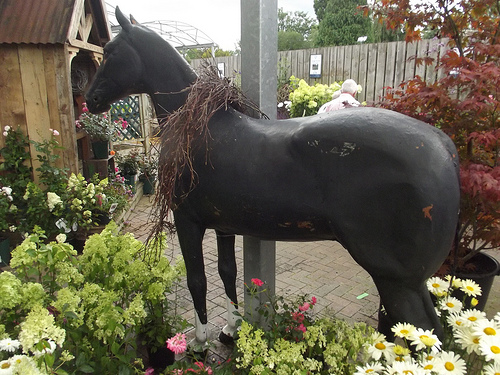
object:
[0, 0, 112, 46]
roof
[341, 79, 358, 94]
hair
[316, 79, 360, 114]
man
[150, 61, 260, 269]
horse collar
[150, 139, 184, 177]
twigs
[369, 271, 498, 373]
daisies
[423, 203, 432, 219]
paint chip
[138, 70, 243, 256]
vines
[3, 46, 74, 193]
wooden wall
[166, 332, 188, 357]
flowers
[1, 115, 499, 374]
garden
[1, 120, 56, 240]
roses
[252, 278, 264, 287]
pink flower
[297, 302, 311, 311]
pink flower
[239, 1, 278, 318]
pillar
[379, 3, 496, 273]
tree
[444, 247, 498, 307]
pot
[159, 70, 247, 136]
horse's neck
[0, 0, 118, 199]
barn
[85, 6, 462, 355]
horse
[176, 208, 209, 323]
leg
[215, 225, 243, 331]
leg